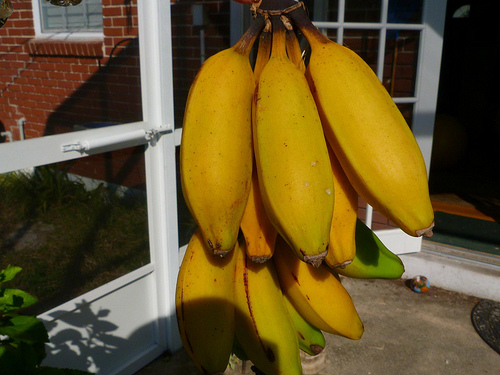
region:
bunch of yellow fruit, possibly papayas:
[175, 7, 439, 371]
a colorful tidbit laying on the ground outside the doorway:
[406, 274, 433, 295]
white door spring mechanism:
[58, 122, 172, 153]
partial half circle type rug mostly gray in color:
[469, 298, 498, 357]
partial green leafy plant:
[3, 265, 50, 371]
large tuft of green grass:
[23, 166, 82, 208]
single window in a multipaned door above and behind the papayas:
[375, 64, 421, 103]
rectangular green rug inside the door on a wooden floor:
[424, 210, 498, 254]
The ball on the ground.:
[415, 273, 427, 295]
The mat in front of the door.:
[470, 299, 499, 355]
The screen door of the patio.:
[6, 1, 166, 359]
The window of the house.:
[32, 5, 95, 35]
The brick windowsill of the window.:
[27, 33, 105, 53]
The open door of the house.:
[280, 5, 425, 257]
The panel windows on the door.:
[304, 0, 414, 232]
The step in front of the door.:
[409, 245, 499, 298]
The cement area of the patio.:
[212, 243, 497, 370]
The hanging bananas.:
[174, 20, 441, 373]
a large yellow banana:
[182, 12, 260, 254]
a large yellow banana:
[256, 18, 337, 264]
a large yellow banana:
[291, 10, 436, 234]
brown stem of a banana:
[290, 8, 325, 46]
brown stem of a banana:
[269, 16, 289, 56]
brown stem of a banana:
[234, 17, 266, 52]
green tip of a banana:
[351, 225, 404, 279]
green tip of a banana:
[297, 326, 324, 358]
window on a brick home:
[38, 3, 101, 36]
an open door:
[418, 5, 499, 254]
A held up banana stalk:
[166, 3, 451, 373]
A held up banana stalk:
[168, 5, 441, 373]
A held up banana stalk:
[173, 4, 435, 374]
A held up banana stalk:
[162, 5, 442, 370]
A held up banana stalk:
[156, 5, 438, 371]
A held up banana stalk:
[151, 3, 439, 373]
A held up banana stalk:
[158, 4, 446, 374]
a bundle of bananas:
[179, 6, 429, 266]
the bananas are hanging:
[162, 3, 433, 368]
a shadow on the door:
[48, 298, 125, 364]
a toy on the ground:
[410, 275, 429, 293]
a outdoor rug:
[472, 300, 499, 346]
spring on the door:
[67, 123, 171, 151]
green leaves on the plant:
[0, 265, 48, 370]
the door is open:
[424, 0, 496, 247]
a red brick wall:
[7, 0, 197, 177]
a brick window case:
[27, 35, 104, 59]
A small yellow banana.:
[258, 50, 336, 275]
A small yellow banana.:
[188, 32, 250, 265]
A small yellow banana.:
[301, 32, 428, 234]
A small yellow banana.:
[276, 237, 375, 357]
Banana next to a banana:
[250, 23, 332, 268]